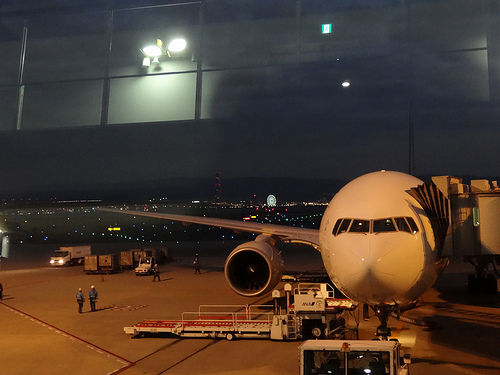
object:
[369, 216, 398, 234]
window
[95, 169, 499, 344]
plane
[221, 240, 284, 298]
engine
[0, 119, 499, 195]
sky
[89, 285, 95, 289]
helmet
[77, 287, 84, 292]
helmet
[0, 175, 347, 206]
mountains distance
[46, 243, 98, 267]
truck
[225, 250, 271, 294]
turbine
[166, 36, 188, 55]
headlights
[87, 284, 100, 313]
person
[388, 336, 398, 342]
wheel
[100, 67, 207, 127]
window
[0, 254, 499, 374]
ground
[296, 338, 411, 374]
vehicle